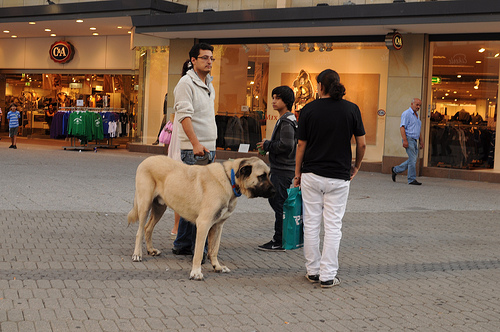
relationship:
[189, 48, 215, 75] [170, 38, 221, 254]
face of man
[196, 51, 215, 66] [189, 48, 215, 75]
glasses on face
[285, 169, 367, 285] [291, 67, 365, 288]
pants on woman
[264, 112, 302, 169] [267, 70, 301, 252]
jacket on kid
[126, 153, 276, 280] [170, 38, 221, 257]
dog by man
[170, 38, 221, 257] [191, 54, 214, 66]
man with glasses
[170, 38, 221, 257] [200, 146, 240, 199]
man holding leash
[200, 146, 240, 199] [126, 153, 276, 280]
leash on dog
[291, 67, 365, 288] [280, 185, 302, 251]
woman holding bag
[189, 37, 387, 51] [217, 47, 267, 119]
lights shining on window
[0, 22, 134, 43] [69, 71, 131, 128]
lights shining on window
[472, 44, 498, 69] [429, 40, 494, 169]
lights shining on store window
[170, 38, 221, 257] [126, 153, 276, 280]
man walking dog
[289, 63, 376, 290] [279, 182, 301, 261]
woman holding bag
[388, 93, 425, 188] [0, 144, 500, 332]
man walking on sidewalk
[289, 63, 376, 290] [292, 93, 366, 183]
woman wearing shirt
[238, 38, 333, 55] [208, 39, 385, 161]
spotlights on store window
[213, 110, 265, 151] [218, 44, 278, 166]
rack in window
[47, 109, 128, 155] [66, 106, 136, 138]
rack with shirts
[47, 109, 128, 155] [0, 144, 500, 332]
rack on sidewalk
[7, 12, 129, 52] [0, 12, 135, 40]
fixtures on ceiling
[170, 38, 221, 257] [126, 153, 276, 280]
man holding onto dog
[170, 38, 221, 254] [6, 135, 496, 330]
man walking on sidewalk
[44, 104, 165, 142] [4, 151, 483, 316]
merchandise on sidewalk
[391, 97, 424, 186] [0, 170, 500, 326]
man on sidewalk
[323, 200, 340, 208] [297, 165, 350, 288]
wrinkle in pants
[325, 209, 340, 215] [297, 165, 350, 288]
wrinkle in pants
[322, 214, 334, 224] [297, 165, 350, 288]
wrinkle in pants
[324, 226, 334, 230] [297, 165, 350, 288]
wrinkle in pants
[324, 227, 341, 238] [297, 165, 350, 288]
wrinkle in pants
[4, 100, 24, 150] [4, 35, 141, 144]
man standing in front of store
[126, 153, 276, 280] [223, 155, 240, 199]
dog wearing blue collar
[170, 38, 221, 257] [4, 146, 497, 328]
man standing in mall area